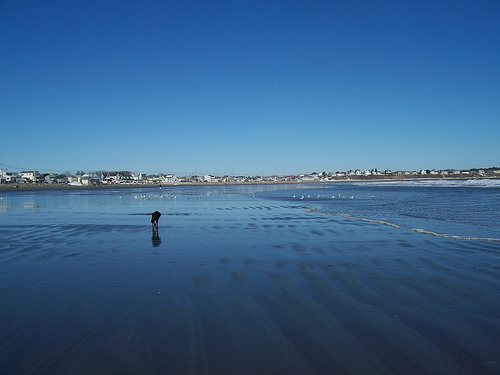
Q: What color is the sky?
A: Blue.